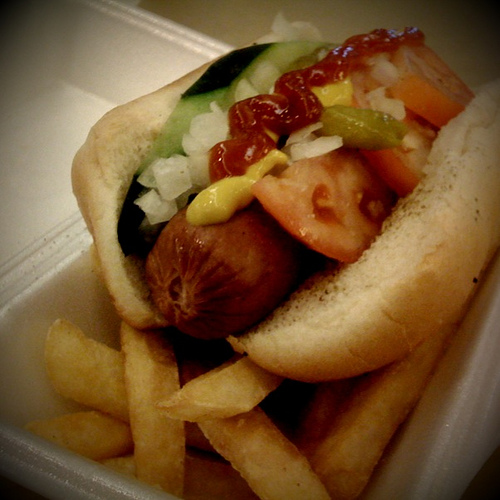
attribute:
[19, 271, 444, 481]
fries — french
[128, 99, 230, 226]
onions — minced